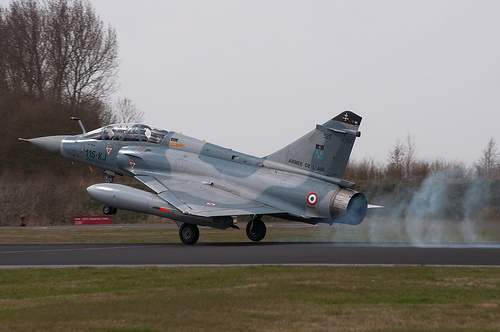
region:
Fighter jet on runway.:
[16, 105, 386, 247]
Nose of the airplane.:
[15, 131, 70, 156]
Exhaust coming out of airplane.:
[325, 172, 495, 243]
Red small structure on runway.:
[65, 215, 115, 225]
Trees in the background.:
[0, 0, 490, 225]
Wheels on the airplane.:
[90, 201, 265, 241]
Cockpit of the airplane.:
[85, 115, 175, 145]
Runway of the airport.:
[0, 240, 490, 265]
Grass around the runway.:
[0, 220, 495, 325]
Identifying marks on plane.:
[80, 146, 114, 165]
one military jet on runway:
[52, 75, 497, 266]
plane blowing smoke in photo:
[231, 88, 498, 268]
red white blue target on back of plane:
[287, 172, 359, 237]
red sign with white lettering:
[50, 198, 128, 232]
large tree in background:
[5, 20, 113, 195]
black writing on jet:
[72, 132, 117, 173]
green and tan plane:
[117, 115, 324, 239]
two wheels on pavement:
[164, 201, 296, 265]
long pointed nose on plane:
[20, 114, 104, 178]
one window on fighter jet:
[85, 107, 196, 158]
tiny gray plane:
[10, 91, 380, 256]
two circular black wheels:
[178, 221, 280, 248]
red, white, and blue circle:
[308, 188, 318, 209]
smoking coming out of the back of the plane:
[312, 172, 497, 247]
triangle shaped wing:
[138, 162, 262, 224]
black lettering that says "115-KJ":
[81, 147, 111, 162]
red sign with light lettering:
[67, 213, 116, 228]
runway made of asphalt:
[5, 238, 499, 265]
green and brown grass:
[4, 266, 499, 329]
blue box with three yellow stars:
[312, 146, 327, 162]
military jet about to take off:
[16, 107, 442, 262]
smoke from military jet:
[343, 168, 487, 255]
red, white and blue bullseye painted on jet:
[301, 186, 326, 210]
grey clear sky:
[218, 49, 343, 105]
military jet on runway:
[33, 85, 395, 275]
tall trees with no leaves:
[2, 23, 112, 152]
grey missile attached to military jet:
[74, 170, 232, 248]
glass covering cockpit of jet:
[75, 115, 184, 155]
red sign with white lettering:
[65, 211, 117, 230]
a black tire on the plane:
[175, 218, 202, 246]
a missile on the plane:
[81, 177, 243, 234]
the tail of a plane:
[257, 102, 365, 180]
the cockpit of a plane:
[78, 117, 171, 144]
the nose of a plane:
[13, 126, 70, 159]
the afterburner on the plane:
[328, 184, 370, 228]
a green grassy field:
[0, 264, 498, 330]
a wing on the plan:
[126, 165, 291, 225]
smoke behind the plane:
[323, 160, 498, 248]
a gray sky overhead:
[0, 0, 499, 170]